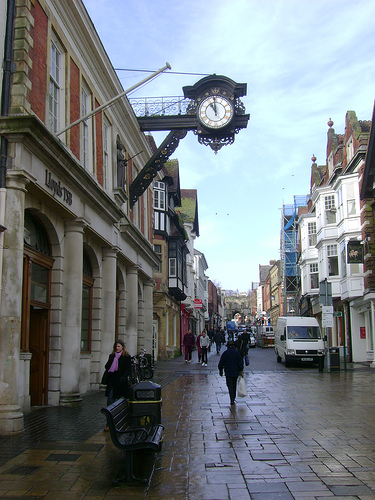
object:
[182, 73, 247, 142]
clock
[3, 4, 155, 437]
building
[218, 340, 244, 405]
person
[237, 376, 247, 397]
bag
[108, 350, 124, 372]
scarf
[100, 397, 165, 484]
bench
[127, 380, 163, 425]
bin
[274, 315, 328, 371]
truck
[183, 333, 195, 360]
clothing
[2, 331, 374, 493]
pavenment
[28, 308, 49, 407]
door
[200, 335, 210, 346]
shirt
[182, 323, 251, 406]
people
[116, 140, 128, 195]
window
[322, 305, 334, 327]
sign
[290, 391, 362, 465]
floor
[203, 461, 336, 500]
crack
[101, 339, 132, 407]
woman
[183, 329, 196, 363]
man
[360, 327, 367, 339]
sign